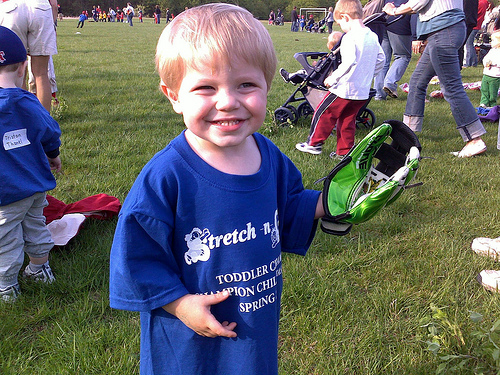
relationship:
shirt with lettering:
[103, 132, 336, 359] [184, 209, 282, 318]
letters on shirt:
[188, 205, 283, 317] [103, 132, 336, 359]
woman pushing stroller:
[401, 0, 492, 170] [283, 40, 352, 140]